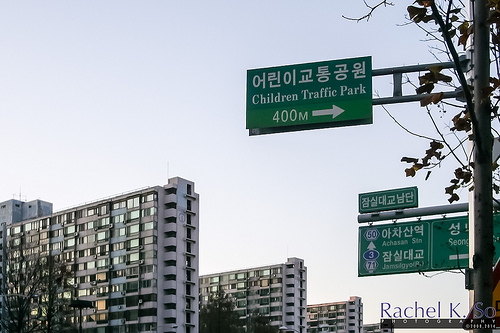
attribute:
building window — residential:
[124, 247, 141, 263]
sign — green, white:
[240, 51, 377, 144]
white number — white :
[268, 106, 300, 131]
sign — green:
[242, 67, 392, 140]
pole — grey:
[368, 62, 478, 114]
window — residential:
[125, 196, 143, 211]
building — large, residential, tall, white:
[4, 170, 205, 330]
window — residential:
[127, 220, 140, 232]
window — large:
[128, 206, 142, 218]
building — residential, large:
[198, 250, 309, 331]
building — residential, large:
[198, 256, 305, 330]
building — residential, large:
[304, 296, 364, 332]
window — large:
[97, 217, 110, 228]